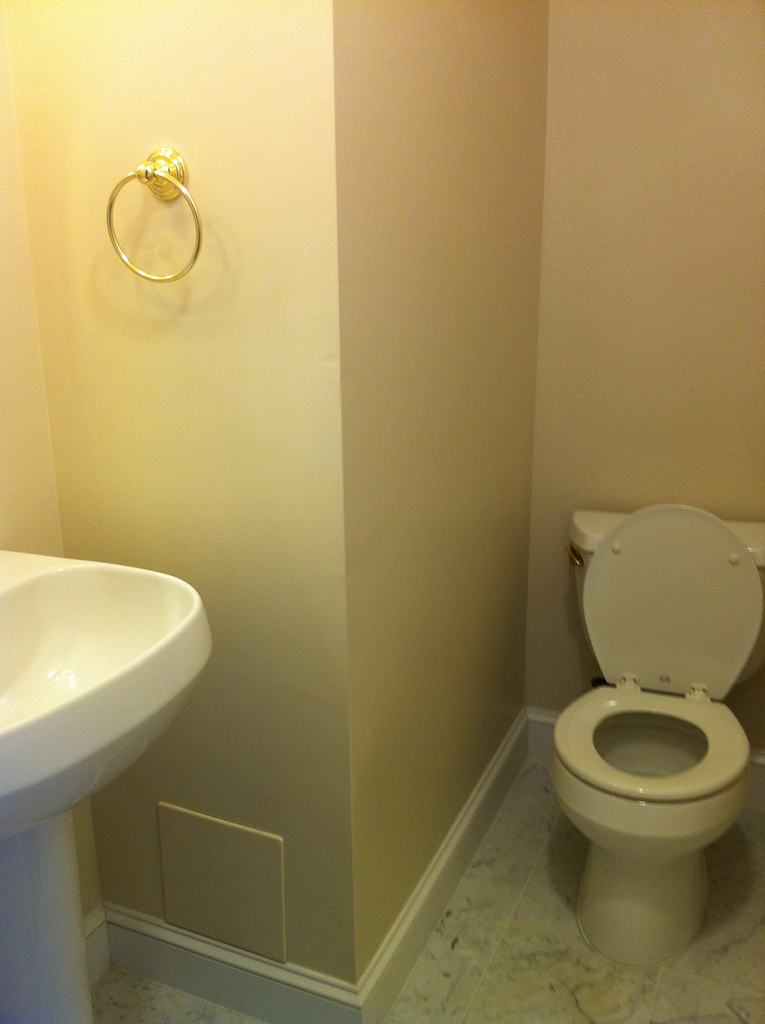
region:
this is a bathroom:
[80, 78, 737, 1002]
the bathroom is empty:
[59, 128, 636, 748]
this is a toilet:
[528, 556, 744, 813]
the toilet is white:
[557, 565, 734, 870]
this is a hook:
[72, 123, 292, 389]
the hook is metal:
[85, 99, 244, 311]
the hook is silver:
[61, 86, 318, 411]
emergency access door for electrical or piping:
[153, 795, 289, 965]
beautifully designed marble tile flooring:
[87, 709, 763, 1017]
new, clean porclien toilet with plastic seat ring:
[548, 509, 762, 963]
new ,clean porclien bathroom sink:
[3, 550, 212, 1019]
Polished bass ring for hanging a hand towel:
[107, 144, 200, 284]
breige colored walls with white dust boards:
[2, 4, 752, 1015]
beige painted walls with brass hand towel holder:
[5, 7, 760, 987]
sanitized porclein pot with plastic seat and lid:
[548, 503, 764, 975]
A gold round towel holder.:
[101, 147, 201, 282]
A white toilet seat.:
[554, 674, 753, 801]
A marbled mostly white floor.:
[94, 753, 762, 1020]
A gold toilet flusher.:
[562, 543, 583, 570]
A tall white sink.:
[1, 546, 209, 1022]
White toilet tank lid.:
[567, 508, 763, 570]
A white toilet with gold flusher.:
[551, 508, 761, 970]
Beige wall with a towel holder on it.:
[1, 1, 356, 991]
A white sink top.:
[2, 547, 214, 835]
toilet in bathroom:
[554, 498, 762, 970]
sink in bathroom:
[0, 545, 232, 1019]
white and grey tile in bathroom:
[89, 759, 764, 1021]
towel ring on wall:
[96, 143, 207, 292]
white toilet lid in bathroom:
[573, 498, 764, 708]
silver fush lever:
[558, 536, 586, 569]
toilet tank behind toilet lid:
[567, 503, 763, 685]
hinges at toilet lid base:
[609, 668, 720, 712]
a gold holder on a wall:
[88, 140, 214, 298]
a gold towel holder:
[72, 138, 214, 321]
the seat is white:
[537, 664, 738, 808]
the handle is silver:
[557, 535, 596, 584]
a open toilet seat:
[529, 468, 749, 992]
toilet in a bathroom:
[542, 500, 762, 971]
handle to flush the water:
[560, 539, 582, 571]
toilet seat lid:
[578, 499, 762, 705]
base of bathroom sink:
[8, 806, 115, 1021]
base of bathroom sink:
[5, 800, 109, 1014]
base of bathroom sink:
[13, 805, 109, 1014]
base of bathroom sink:
[1, 803, 109, 1009]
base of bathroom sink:
[5, 809, 109, 1019]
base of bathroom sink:
[3, 797, 103, 1019]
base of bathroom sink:
[1, 803, 103, 1020]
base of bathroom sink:
[5, 791, 105, 1020]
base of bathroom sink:
[9, 800, 96, 1019]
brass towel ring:
[97, 140, 215, 292]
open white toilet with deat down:
[535, 458, 761, 980]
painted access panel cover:
[147, 785, 304, 972]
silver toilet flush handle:
[560, 530, 588, 579]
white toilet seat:
[530, 502, 760, 810]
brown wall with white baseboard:
[332, 0, 536, 1021]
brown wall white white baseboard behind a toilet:
[525, 0, 762, 1001]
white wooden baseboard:
[93, 896, 383, 1020]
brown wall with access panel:
[19, 9, 356, 1019]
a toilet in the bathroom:
[508, 508, 748, 960]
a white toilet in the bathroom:
[508, 542, 758, 999]